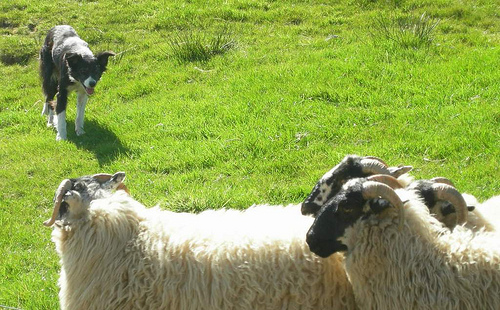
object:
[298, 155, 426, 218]
sheep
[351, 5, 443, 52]
grass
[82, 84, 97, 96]
mouth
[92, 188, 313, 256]
sunlight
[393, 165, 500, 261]
sunlight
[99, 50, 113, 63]
black ear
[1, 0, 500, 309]
field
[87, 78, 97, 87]
nose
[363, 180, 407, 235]
horn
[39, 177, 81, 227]
horn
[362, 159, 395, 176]
horn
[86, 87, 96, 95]
tongue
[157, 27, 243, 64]
grass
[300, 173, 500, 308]
sheep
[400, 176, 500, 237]
sheep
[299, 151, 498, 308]
two sheep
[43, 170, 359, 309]
sheep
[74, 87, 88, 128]
leg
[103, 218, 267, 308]
fur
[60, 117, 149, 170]
dog's shadow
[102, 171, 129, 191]
ear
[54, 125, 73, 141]
paws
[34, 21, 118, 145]
dog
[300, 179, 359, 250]
face